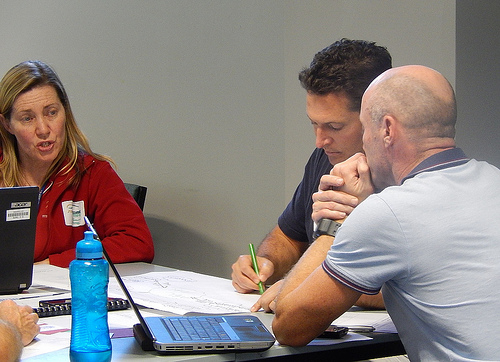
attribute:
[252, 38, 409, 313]
man — balding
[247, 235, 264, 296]
pen — green, metallic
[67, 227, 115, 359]
water bottle — plastic, blue, see thru, nearly empty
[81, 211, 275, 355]
laptop — black, being used, open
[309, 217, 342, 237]
watch — black, plastic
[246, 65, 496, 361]
man — balding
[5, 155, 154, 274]
sweatshirt — red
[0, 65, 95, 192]
hair — blonde, long, straight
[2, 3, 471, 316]
wall — smooth, white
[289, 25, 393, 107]
hair — brown